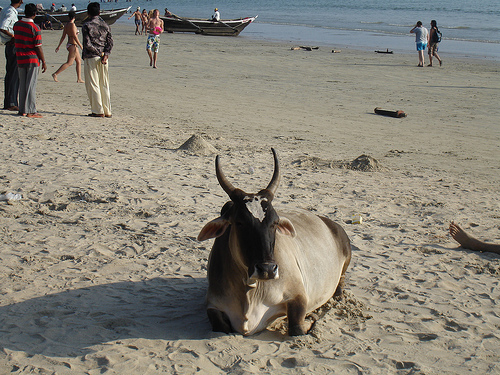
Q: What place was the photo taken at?
A: It was taken at the beach.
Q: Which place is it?
A: It is a beach.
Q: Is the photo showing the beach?
A: Yes, it is showing the beach.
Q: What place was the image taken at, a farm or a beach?
A: It was taken at a beach.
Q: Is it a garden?
A: No, it is a beach.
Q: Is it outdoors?
A: Yes, it is outdoors.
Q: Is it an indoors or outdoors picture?
A: It is outdoors.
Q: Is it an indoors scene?
A: No, it is outdoors.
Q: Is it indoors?
A: No, it is outdoors.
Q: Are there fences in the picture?
A: No, there are no fences.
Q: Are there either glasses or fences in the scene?
A: No, there are no fences or glasses.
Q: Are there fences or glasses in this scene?
A: No, there are no fences or glasses.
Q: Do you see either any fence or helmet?
A: No, there are no fences or helmets.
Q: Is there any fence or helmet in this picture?
A: No, there are no fences or helmets.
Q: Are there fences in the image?
A: No, there are no fences.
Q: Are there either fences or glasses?
A: No, there are no fences or glasses.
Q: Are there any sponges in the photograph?
A: No, there are no sponges.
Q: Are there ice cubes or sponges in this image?
A: No, there are no sponges or ice cubes.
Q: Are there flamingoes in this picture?
A: No, there are no flamingoes.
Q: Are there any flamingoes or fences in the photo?
A: No, there are no flamingoes or fences.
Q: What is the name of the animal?
A: The animal is a bull.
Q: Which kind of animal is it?
A: The animal is a bull.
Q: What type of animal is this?
A: This is a bull.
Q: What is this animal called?
A: This is a bull.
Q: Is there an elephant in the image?
A: No, there are no elephants.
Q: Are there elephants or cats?
A: No, there are no elephants or cats.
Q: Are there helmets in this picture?
A: No, there are no helmets.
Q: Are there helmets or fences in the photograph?
A: No, there are no helmets or fences.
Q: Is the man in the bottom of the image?
A: No, the man is in the top of the image.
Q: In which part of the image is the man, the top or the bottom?
A: The man is in the top of the image.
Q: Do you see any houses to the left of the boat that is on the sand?
A: No, there is a man to the left of the boat.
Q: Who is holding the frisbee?
A: The man is holding the frisbee.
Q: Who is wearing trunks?
A: The man is wearing trunks.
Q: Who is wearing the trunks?
A: The man is wearing trunks.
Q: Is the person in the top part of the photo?
A: Yes, the person is in the top of the image.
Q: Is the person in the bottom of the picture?
A: No, the person is in the top of the image.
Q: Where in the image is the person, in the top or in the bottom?
A: The person is in the top of the image.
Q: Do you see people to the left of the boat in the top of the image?
A: Yes, there is a person to the left of the boat.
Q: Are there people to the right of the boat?
A: No, the person is to the left of the boat.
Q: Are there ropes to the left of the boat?
A: No, there is a person to the left of the boat.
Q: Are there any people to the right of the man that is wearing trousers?
A: Yes, there is a person to the right of the man.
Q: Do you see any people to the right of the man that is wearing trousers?
A: Yes, there is a person to the right of the man.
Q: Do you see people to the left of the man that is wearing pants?
A: No, the person is to the right of the man.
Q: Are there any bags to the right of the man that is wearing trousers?
A: No, there is a person to the right of the man.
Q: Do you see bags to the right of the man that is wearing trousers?
A: No, there is a person to the right of the man.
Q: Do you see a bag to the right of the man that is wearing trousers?
A: No, there is a person to the right of the man.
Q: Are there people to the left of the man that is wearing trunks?
A: Yes, there is a person to the left of the man.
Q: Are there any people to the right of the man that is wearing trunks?
A: No, the person is to the left of the man.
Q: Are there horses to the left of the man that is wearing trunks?
A: No, there is a person to the left of the man.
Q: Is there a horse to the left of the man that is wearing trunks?
A: No, there is a person to the left of the man.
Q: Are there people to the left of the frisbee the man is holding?
A: Yes, there is a person to the left of the frisbee.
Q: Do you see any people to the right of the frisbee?
A: No, the person is to the left of the frisbee.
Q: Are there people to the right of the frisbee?
A: No, the person is to the left of the frisbee.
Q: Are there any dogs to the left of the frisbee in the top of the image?
A: No, there is a person to the left of the frisbee.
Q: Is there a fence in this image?
A: No, there are no fences.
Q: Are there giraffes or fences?
A: No, there are no fences or giraffes.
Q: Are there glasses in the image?
A: No, there are no glasses.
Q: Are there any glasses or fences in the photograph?
A: No, there are no glasses or fences.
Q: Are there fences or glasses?
A: No, there are no glasses or fences.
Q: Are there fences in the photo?
A: No, there are no fences.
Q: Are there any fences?
A: No, there are no fences.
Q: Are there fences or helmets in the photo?
A: No, there are no fences or helmets.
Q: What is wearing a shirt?
A: The pants are wearing a shirt.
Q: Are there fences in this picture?
A: No, there are no fences.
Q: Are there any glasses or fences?
A: No, there are no fences or glasses.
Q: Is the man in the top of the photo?
A: Yes, the man is in the top of the image.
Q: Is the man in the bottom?
A: No, the man is in the top of the image.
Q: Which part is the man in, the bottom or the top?
A: The man is in the top of the image.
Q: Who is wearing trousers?
A: The man is wearing trousers.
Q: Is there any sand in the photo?
A: Yes, there is sand.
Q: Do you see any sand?
A: Yes, there is sand.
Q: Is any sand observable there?
A: Yes, there is sand.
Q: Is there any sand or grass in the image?
A: Yes, there is sand.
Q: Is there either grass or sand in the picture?
A: Yes, there is sand.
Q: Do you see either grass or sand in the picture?
A: Yes, there is sand.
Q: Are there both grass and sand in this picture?
A: No, there is sand but no grass.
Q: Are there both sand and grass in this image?
A: No, there is sand but no grass.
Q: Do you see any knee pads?
A: No, there are no knee pads.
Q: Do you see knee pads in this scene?
A: No, there are no knee pads.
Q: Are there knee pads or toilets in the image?
A: No, there are no knee pads or toilets.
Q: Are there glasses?
A: No, there are no glasses.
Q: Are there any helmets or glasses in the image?
A: No, there are no glasses or helmets.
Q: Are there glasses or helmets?
A: No, there are no glasses or helmets.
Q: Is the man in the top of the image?
A: Yes, the man is in the top of the image.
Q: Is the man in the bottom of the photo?
A: No, the man is in the top of the image.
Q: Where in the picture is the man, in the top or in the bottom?
A: The man is in the top of the image.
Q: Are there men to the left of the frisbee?
A: Yes, there is a man to the left of the frisbee.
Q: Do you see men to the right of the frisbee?
A: No, the man is to the left of the frisbee.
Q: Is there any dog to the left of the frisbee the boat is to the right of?
A: No, there is a man to the left of the frisbee.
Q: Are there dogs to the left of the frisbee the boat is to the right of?
A: No, there is a man to the left of the frisbee.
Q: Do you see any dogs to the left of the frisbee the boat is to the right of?
A: No, there is a man to the left of the frisbee.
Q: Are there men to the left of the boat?
A: Yes, there is a man to the left of the boat.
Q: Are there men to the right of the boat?
A: No, the man is to the left of the boat.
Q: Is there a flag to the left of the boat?
A: No, there is a man to the left of the boat.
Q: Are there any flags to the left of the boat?
A: No, there is a man to the left of the boat.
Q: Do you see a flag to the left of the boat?
A: No, there is a man to the left of the boat.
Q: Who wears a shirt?
A: The man wears a shirt.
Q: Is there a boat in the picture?
A: Yes, there is a boat.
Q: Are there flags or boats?
A: Yes, there is a boat.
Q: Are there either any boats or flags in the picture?
A: Yes, there is a boat.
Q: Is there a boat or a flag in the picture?
A: Yes, there is a boat.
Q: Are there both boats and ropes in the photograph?
A: No, there is a boat but no ropes.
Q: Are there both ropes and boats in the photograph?
A: No, there is a boat but no ropes.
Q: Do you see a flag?
A: No, there are no flags.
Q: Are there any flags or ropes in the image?
A: No, there are no flags or ropes.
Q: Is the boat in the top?
A: Yes, the boat is in the top of the image.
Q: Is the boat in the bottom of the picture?
A: No, the boat is in the top of the image.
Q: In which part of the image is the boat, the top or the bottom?
A: The boat is in the top of the image.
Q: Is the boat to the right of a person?
A: Yes, the boat is to the right of a person.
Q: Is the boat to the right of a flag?
A: No, the boat is to the right of a person.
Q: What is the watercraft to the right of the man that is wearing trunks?
A: The watercraft is a boat.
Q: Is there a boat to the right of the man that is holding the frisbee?
A: Yes, there is a boat to the right of the man.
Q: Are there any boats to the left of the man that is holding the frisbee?
A: No, the boat is to the right of the man.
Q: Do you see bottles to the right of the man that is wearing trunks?
A: No, there is a boat to the right of the man.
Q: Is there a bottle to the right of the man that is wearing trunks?
A: No, there is a boat to the right of the man.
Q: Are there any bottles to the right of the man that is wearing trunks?
A: No, there is a boat to the right of the man.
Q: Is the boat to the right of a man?
A: Yes, the boat is to the right of a man.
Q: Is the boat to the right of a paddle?
A: No, the boat is to the right of a man.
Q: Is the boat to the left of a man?
A: No, the boat is to the right of a man.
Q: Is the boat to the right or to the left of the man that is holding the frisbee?
A: The boat is to the right of the man.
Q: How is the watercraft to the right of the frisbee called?
A: The watercraft is a boat.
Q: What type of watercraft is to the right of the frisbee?
A: The watercraft is a boat.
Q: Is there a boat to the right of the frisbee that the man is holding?
A: Yes, there is a boat to the right of the frisbee.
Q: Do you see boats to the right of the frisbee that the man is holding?
A: Yes, there is a boat to the right of the frisbee.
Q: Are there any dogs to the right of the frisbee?
A: No, there is a boat to the right of the frisbee.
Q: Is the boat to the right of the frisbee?
A: Yes, the boat is to the right of the frisbee.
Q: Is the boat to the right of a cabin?
A: No, the boat is to the right of the frisbee.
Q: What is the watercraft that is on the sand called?
A: The watercraft is a boat.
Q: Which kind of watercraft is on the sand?
A: The watercraft is a boat.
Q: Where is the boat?
A: The boat is on the sand.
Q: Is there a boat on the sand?
A: Yes, there is a boat on the sand.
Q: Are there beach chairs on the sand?
A: No, there is a boat on the sand.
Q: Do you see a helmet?
A: No, there are no helmets.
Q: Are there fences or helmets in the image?
A: No, there are no helmets or fences.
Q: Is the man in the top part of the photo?
A: Yes, the man is in the top of the image.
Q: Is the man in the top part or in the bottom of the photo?
A: The man is in the top of the image.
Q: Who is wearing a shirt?
A: The man is wearing a shirt.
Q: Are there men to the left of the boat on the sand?
A: Yes, there is a man to the left of the boat.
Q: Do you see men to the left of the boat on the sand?
A: Yes, there is a man to the left of the boat.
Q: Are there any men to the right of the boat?
A: No, the man is to the left of the boat.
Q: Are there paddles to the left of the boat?
A: No, there is a man to the left of the boat.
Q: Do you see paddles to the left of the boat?
A: No, there is a man to the left of the boat.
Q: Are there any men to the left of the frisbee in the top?
A: Yes, there is a man to the left of the frisbee.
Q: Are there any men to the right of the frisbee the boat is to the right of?
A: No, the man is to the left of the frisbee.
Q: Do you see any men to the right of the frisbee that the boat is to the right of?
A: No, the man is to the left of the frisbee.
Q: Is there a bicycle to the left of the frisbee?
A: No, there is a man to the left of the frisbee.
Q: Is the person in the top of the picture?
A: Yes, the person is in the top of the image.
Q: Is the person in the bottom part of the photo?
A: No, the person is in the top of the image.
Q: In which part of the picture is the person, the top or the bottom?
A: The person is in the top of the image.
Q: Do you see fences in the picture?
A: No, there are no fences.